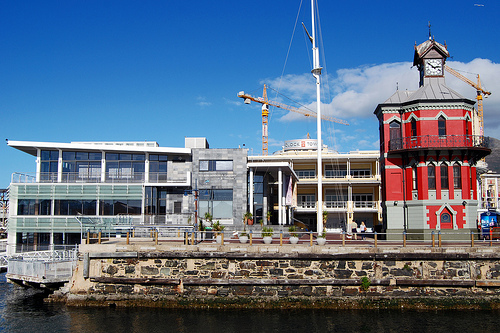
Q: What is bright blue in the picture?
A: The sky.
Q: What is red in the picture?
A: A building.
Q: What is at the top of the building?
A: A clock.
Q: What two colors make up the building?
A: White and green.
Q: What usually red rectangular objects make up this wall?
A: Bricks.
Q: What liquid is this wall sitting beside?
A: Water.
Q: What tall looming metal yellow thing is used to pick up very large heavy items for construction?
A: Crane.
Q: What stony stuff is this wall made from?
A: Rock.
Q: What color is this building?
A: Red.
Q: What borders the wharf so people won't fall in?
A: Railing.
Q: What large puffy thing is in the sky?
A: Cloud.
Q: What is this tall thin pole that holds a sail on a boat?
A: Mast.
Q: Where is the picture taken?
A: A boardwalk.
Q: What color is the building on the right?
A: Red and grey.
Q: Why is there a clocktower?
A: To tell the time.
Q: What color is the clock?
A: White and black.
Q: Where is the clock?
A: On top of the red and grey building.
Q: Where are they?
A: By the water.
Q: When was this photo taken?
A: During daylight hours.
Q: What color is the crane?
A: Yellow.